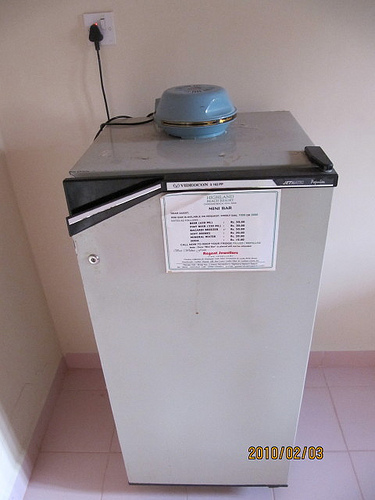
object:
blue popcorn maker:
[151, 82, 239, 142]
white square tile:
[34, 453, 105, 500]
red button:
[100, 18, 105, 21]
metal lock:
[86, 253, 101, 267]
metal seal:
[157, 112, 238, 129]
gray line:
[34, 447, 109, 457]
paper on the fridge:
[158, 189, 280, 272]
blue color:
[151, 82, 239, 116]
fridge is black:
[62, 106, 338, 491]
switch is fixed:
[82, 9, 116, 50]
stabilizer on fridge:
[150, 82, 239, 143]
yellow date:
[247, 443, 324, 462]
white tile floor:
[34, 358, 374, 500]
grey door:
[60, 181, 333, 490]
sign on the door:
[158, 187, 283, 275]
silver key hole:
[87, 254, 100, 266]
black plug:
[85, 23, 103, 52]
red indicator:
[94, 21, 99, 26]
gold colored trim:
[155, 115, 244, 127]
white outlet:
[82, 10, 119, 48]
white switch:
[79, 10, 118, 48]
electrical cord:
[96, 51, 152, 135]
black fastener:
[303, 142, 334, 171]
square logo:
[160, 188, 280, 275]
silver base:
[155, 109, 237, 128]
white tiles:
[24, 451, 108, 499]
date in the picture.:
[245, 445, 324, 460]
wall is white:
[1, 0, 373, 350]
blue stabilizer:
[152, 78, 240, 142]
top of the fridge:
[68, 110, 331, 174]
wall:
[0, 0, 375, 113]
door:
[66, 180, 332, 490]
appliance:
[153, 83, 240, 141]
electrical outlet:
[82, 8, 118, 48]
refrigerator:
[58, 81, 342, 490]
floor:
[22, 358, 375, 500]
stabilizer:
[150, 79, 239, 142]